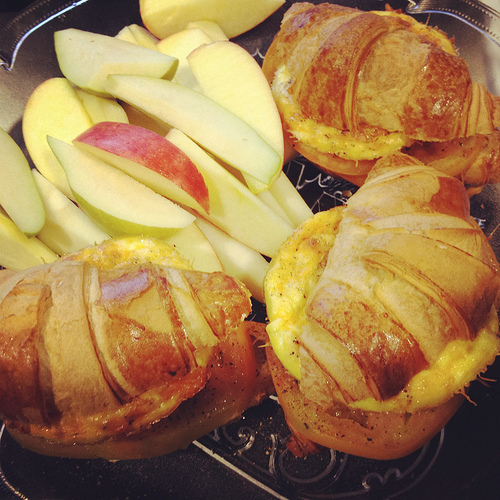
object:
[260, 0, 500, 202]
croissant sandwich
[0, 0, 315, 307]
apples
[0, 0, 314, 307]
skin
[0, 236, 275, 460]
bacon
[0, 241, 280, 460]
croissant sandwich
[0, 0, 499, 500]
platter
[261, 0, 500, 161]
top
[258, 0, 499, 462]
sandwiches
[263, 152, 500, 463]
eggs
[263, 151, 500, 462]
bread